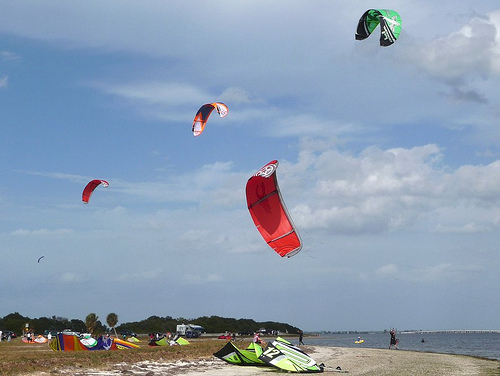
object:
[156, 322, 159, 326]
leaves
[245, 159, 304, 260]
parasail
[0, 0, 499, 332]
sky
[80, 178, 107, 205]
parasail